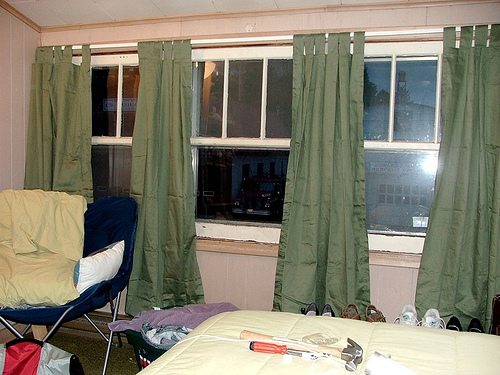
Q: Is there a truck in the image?
A: No, there are no trucks.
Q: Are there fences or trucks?
A: No, there are no trucks or fences.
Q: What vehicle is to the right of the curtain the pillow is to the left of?
A: The vehicle is a car.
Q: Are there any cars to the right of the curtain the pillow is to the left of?
A: Yes, there is a car to the right of the curtain.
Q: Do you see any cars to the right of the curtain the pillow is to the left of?
A: Yes, there is a car to the right of the curtain.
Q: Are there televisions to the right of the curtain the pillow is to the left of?
A: No, there is a car to the right of the curtain.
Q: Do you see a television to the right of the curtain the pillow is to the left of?
A: No, there is a car to the right of the curtain.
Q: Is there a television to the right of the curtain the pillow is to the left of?
A: No, there is a car to the right of the curtain.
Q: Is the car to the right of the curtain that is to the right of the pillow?
A: Yes, the car is to the right of the curtain.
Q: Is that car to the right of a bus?
A: No, the car is to the right of the curtain.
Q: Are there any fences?
A: No, there are no fences.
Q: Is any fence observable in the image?
A: No, there are no fences.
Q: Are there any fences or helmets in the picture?
A: No, there are no fences or helmets.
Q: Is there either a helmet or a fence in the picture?
A: No, there are no fences or helmets.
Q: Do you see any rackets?
A: No, there are no rackets.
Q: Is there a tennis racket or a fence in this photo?
A: No, there are no rackets or fences.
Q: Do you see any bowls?
A: No, there are no bowls.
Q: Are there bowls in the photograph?
A: No, there are no bowls.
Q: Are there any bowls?
A: No, there are no bowls.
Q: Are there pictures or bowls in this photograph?
A: No, there are no bowls or pictures.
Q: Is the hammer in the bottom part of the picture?
A: Yes, the hammer is in the bottom of the image.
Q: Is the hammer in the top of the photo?
A: No, the hammer is in the bottom of the image.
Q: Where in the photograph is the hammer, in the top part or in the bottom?
A: The hammer is in the bottom of the image.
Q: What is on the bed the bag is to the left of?
A: The hammer is on the bed.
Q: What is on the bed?
A: The hammer is on the bed.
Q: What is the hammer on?
A: The hammer is on the bed.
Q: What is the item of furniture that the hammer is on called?
A: The piece of furniture is a bed.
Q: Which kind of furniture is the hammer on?
A: The hammer is on the bed.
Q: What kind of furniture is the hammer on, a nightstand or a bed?
A: The hammer is on a bed.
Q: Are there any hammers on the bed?
A: Yes, there is a hammer on the bed.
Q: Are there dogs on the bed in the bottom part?
A: No, there is a hammer on the bed.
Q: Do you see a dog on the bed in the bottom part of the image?
A: No, there is a hammer on the bed.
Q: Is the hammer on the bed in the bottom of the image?
A: Yes, the hammer is on the bed.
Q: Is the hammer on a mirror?
A: No, the hammer is on the bed.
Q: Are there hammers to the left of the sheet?
A: Yes, there is a hammer to the left of the sheet.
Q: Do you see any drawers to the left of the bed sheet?
A: No, there is a hammer to the left of the bed sheet.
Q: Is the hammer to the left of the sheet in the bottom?
A: Yes, the hammer is to the left of the bed sheet.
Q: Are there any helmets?
A: No, there are no helmets.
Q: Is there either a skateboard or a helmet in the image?
A: No, there are no helmets or skateboards.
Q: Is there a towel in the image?
A: Yes, there is a towel.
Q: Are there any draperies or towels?
A: Yes, there is a towel.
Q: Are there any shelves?
A: No, there are no shelves.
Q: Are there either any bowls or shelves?
A: No, there are no shelves or bowls.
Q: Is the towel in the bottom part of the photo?
A: Yes, the towel is in the bottom of the image.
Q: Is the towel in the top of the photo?
A: No, the towel is in the bottom of the image.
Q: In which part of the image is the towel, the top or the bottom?
A: The towel is in the bottom of the image.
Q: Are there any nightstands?
A: No, there are no nightstands.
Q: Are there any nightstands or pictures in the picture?
A: No, there are no nightstands or pictures.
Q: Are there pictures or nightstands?
A: No, there are no nightstands or pictures.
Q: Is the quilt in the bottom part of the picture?
A: Yes, the quilt is in the bottom of the image.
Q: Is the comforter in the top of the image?
A: No, the comforter is in the bottom of the image.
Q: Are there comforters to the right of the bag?
A: Yes, there is a comforter to the right of the bag.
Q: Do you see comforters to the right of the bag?
A: Yes, there is a comforter to the right of the bag.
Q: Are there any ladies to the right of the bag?
A: No, there is a comforter to the right of the bag.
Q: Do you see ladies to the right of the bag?
A: No, there is a comforter to the right of the bag.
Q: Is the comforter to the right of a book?
A: No, the comforter is to the right of a bag.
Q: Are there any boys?
A: No, there are no boys.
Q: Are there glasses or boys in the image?
A: No, there are no boys or glasses.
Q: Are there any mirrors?
A: No, there are no mirrors.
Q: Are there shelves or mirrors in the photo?
A: No, there are no mirrors or shelves.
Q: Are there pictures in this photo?
A: No, there are no pictures.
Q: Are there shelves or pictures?
A: No, there are no pictures or shelves.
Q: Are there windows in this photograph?
A: Yes, there is a window.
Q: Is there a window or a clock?
A: Yes, there is a window.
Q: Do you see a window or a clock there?
A: Yes, there is a window.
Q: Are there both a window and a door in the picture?
A: No, there is a window but no doors.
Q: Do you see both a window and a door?
A: No, there is a window but no doors.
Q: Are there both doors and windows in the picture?
A: No, there is a window but no doors.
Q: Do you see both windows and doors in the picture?
A: No, there is a window but no doors.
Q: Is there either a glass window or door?
A: Yes, there is a glass window.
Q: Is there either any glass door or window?
A: Yes, there is a glass window.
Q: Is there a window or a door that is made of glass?
A: Yes, the window is made of glass.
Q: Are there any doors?
A: No, there are no doors.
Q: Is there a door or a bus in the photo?
A: No, there are no doors or buses.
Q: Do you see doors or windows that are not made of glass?
A: No, there is a window but it is made of glass.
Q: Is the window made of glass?
A: Yes, the window is made of glass.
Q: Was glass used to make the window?
A: Yes, the window is made of glass.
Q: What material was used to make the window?
A: The window is made of glass.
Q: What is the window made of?
A: The window is made of glass.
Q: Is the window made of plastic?
A: No, the window is made of glass.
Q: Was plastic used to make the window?
A: No, the window is made of glass.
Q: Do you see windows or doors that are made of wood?
A: No, there is a window but it is made of glass.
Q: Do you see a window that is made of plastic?
A: No, there is a window but it is made of glass.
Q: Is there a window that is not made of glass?
A: No, there is a window but it is made of glass.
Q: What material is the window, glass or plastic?
A: The window is made of glass.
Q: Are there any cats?
A: No, there are no cats.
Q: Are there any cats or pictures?
A: No, there are no cats or pictures.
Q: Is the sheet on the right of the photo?
A: Yes, the sheet is on the right of the image.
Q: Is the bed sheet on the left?
A: No, the bed sheet is on the right of the image.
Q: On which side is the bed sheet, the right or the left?
A: The bed sheet is on the right of the image.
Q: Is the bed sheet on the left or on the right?
A: The bed sheet is on the right of the image.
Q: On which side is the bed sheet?
A: The bed sheet is on the right of the image.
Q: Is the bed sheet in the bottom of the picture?
A: Yes, the bed sheet is in the bottom of the image.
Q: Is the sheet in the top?
A: No, the sheet is in the bottom of the image.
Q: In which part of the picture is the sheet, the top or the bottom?
A: The sheet is in the bottom of the image.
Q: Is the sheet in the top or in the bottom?
A: The sheet is in the bottom of the image.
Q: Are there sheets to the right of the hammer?
A: Yes, there is a sheet to the right of the hammer.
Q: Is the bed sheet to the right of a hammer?
A: Yes, the bed sheet is to the right of a hammer.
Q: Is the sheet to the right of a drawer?
A: No, the sheet is to the right of a hammer.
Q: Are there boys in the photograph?
A: No, there are no boys.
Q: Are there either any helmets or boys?
A: No, there are no boys or helmets.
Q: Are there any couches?
A: No, there are no couches.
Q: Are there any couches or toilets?
A: No, there are no couches or toilets.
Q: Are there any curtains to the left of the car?
A: Yes, there is a curtain to the left of the car.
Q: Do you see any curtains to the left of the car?
A: Yes, there is a curtain to the left of the car.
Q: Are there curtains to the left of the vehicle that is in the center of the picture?
A: Yes, there is a curtain to the left of the car.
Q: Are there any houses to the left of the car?
A: No, there is a curtain to the left of the car.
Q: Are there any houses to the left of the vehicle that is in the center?
A: No, there is a curtain to the left of the car.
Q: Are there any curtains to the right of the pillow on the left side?
A: Yes, there is a curtain to the right of the pillow.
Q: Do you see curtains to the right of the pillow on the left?
A: Yes, there is a curtain to the right of the pillow.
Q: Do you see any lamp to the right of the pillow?
A: No, there is a curtain to the right of the pillow.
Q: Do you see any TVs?
A: No, there are no tvs.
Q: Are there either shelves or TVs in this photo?
A: No, there are no TVs or shelves.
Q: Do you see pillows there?
A: Yes, there is a pillow.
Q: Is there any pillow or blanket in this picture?
A: Yes, there is a pillow.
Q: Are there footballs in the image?
A: No, there are no footballs.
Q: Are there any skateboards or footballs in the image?
A: No, there are no footballs or skateboards.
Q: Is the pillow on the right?
A: No, the pillow is on the left of the image.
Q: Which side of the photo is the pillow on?
A: The pillow is on the left of the image.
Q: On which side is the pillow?
A: The pillow is on the left of the image.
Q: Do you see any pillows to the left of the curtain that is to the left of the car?
A: Yes, there is a pillow to the left of the curtain.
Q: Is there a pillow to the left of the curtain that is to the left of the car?
A: Yes, there is a pillow to the left of the curtain.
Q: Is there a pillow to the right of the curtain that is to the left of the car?
A: No, the pillow is to the left of the curtain.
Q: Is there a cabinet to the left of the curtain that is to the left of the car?
A: No, there is a pillow to the left of the curtain.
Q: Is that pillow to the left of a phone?
A: No, the pillow is to the left of a curtain.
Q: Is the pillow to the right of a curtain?
A: No, the pillow is to the left of a curtain.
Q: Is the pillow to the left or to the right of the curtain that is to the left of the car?
A: The pillow is to the left of the curtain.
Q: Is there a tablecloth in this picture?
A: No, there are no tablecloths.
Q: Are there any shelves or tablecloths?
A: No, there are no tablecloths or shelves.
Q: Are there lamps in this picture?
A: No, there are no lamps.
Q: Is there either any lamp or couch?
A: No, there are no lamps or couches.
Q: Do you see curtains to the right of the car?
A: Yes, there is a curtain to the right of the car.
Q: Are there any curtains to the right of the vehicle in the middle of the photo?
A: Yes, there is a curtain to the right of the car.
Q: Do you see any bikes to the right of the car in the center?
A: No, there is a curtain to the right of the car.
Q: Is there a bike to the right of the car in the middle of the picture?
A: No, there is a curtain to the right of the car.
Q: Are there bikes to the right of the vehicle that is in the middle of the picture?
A: No, there is a curtain to the right of the car.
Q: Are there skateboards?
A: No, there are no skateboards.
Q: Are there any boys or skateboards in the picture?
A: No, there are no skateboards or boys.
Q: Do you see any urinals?
A: No, there are no urinals.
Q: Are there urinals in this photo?
A: No, there are no urinals.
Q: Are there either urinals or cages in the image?
A: No, there are no urinals or cages.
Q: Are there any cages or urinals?
A: No, there are no urinals or cages.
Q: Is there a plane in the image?
A: No, there are no airplanes.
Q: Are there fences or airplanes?
A: No, there are no airplanes or fences.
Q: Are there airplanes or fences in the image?
A: No, there are no airplanes or fences.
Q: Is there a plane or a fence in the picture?
A: No, there are no airplanes or fences.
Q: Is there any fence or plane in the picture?
A: No, there are no airplanes or fences.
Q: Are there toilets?
A: No, there are no toilets.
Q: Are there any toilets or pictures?
A: No, there are no toilets or pictures.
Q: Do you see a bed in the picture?
A: Yes, there is a bed.